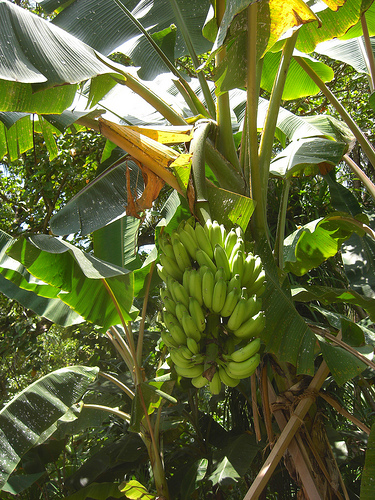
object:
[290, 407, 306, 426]
rope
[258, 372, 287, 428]
planks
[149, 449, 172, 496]
stem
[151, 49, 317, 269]
plant stalks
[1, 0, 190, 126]
leaf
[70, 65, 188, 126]
sunlight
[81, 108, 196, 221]
yellow leaf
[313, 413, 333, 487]
yellow leaf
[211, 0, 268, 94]
leaf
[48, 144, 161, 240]
leaf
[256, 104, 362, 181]
leaf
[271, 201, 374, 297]
leaf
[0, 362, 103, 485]
leaf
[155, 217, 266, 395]
bananas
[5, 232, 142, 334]
leaf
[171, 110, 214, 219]
branch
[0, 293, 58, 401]
tree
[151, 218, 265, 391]
banana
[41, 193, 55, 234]
twigs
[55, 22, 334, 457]
banana tree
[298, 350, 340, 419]
wood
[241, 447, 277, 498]
wood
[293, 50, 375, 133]
tree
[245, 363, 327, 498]
post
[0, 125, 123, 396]
forest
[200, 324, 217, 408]
stem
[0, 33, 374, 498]
field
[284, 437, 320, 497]
planks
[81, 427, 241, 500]
background